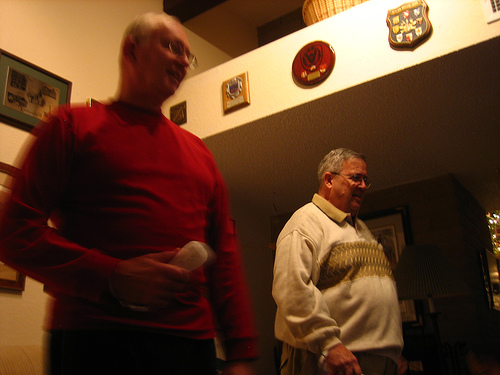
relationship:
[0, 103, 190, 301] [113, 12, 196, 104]
arm below head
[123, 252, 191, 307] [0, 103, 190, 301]
hand attached to arm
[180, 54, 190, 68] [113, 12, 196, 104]
nose on head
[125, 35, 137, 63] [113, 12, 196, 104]
ear on head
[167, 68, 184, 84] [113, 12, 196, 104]
mouth on head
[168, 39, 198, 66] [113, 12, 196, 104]
glasses are on head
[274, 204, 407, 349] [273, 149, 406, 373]
sweater on guy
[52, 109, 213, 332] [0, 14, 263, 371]
shirt on man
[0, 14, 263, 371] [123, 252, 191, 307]
man above hand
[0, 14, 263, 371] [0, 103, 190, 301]
man above arm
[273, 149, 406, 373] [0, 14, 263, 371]
guy next to man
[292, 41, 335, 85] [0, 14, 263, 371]
monument above man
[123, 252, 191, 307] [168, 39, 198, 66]
hand below glasses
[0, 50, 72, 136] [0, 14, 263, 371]
frame above man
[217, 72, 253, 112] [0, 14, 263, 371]
wall peice above man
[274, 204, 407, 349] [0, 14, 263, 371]
sweater next to man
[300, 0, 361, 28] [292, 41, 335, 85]
basket above monument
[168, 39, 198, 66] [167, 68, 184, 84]
glasses are above mouth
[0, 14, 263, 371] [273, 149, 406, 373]
man next to guy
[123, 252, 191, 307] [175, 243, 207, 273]
hand holding remote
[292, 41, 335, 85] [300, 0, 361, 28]
monument below basket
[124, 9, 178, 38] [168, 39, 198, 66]
hair above glasses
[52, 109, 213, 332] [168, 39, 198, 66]
shirt below glasses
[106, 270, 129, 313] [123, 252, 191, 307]
clasp attached to hand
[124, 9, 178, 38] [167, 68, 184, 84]
hair above mouth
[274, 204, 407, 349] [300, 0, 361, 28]
sweater below basket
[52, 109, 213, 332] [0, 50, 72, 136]
shirt below frame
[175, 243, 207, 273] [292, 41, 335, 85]
remote below monument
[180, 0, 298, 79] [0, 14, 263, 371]
nook above man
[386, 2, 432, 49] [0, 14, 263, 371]
plaque above man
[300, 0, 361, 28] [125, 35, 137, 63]
basket above ear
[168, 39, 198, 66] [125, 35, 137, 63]
glasses are level with ear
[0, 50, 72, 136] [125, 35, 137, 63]
frame above ear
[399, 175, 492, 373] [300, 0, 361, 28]
dark below basket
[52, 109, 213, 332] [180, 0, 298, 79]
shirt below nook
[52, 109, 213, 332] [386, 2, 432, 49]
shirt below plaque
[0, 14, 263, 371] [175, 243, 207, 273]
man holding remote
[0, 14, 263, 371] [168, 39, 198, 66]
man has glasses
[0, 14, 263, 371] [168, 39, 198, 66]
man wearing glasses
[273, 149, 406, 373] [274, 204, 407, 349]
guy wearing sweater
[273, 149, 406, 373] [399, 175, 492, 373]
guy to right of dark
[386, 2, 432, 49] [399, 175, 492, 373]
plaque above dark